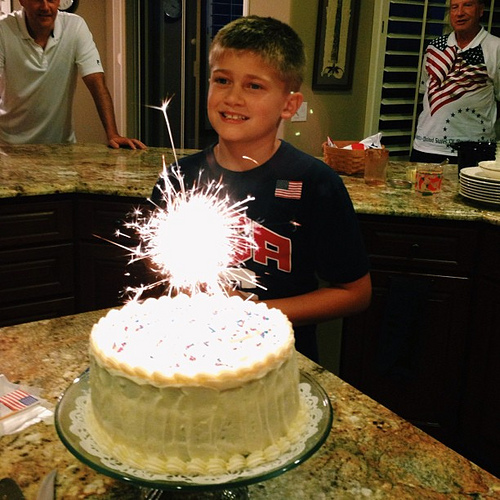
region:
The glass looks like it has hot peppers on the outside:
[413, 166, 448, 210]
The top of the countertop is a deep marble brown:
[351, 456, 407, 495]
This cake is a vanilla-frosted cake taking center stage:
[133, 285, 288, 466]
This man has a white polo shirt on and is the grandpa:
[13, 12, 104, 142]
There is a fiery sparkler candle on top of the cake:
[152, 162, 243, 329]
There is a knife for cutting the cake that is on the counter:
[37, 467, 52, 485]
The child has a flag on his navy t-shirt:
[275, 180, 309, 203]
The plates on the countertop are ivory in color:
[466, 172, 486, 214]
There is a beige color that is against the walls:
[91, 19, 103, 46]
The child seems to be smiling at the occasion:
[211, 20, 313, 154]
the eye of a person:
[247, 79, 263, 91]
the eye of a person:
[211, 74, 233, 89]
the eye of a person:
[461, 2, 473, 10]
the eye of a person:
[448, 3, 458, 12]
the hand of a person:
[75, 32, 145, 162]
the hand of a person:
[229, 177, 375, 326]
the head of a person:
[198, 15, 307, 142]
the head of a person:
[15, 0, 61, 31]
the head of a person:
[445, 4, 489, 33]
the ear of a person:
[280, 86, 314, 128]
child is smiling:
[141, 12, 373, 324]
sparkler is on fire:
[88, 90, 268, 325]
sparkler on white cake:
[87, 291, 309, 476]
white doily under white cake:
[67, 380, 323, 485]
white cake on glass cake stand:
[55, 365, 334, 498]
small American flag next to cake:
[0, 387, 41, 419]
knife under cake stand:
[33, 467, 58, 499]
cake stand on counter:
[0, 301, 499, 498]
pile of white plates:
[457, 166, 499, 206]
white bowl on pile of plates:
[477, 157, 499, 178]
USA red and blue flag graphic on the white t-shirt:
[425, 37, 495, 109]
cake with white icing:
[90, 293, 297, 468]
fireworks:
[126, 164, 259, 294]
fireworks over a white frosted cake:
[90, 153, 307, 475]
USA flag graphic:
[1, 388, 38, 410]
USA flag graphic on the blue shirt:
[273, 173, 310, 202]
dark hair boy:
[203, 10, 310, 167]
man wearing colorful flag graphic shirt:
[421, 2, 499, 142]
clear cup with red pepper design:
[412, 157, 445, 205]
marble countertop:
[328, 432, 431, 498]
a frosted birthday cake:
[83, 290, 330, 465]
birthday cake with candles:
[114, 173, 269, 360]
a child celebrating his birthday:
[77, 17, 397, 468]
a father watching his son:
[0, 2, 140, 164]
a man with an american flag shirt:
[415, 2, 498, 107]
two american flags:
[415, 34, 491, 109]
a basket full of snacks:
[320, 126, 392, 183]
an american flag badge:
[268, 162, 308, 215]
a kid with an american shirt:
[186, 19, 374, 308]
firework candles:
[126, 166, 274, 301]